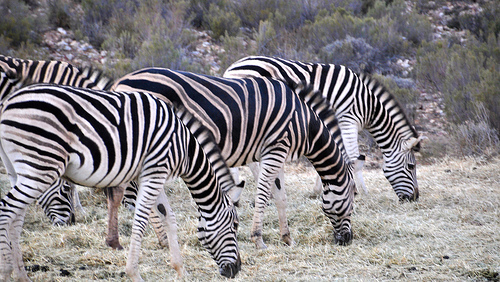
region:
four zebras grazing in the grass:
[1, 20, 441, 277]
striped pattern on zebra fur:
[207, 93, 299, 136]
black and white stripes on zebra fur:
[55, 103, 144, 154]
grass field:
[8, 158, 498, 275]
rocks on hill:
[41, 24, 105, 64]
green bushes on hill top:
[5, 0, 499, 135]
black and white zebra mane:
[280, 73, 365, 180]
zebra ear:
[405, 129, 426, 156]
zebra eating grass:
[2, 77, 249, 280]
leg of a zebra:
[0, 191, 11, 281]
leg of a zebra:
[3, 202, 55, 280]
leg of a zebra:
[92, 185, 139, 267]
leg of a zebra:
[105, 185, 170, 277]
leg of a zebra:
[150, 181, 202, 281]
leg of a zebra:
[263, 176, 308, 250]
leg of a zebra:
[337, 139, 369, 209]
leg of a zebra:
[87, 186, 122, 246]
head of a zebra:
[175, 162, 263, 277]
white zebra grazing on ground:
[0, 84, 240, 275]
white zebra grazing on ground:
[112, 68, 357, 248]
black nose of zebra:
[215, 254, 244, 276]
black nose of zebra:
[332, 227, 352, 248]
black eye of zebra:
[230, 222, 240, 231]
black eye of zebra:
[352, 187, 360, 198]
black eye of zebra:
[404, 159, 414, 169]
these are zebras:
[12, 40, 438, 279]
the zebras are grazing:
[11, 28, 450, 268]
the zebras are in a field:
[7, 30, 481, 280]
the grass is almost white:
[12, 145, 493, 275]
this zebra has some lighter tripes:
[132, 40, 356, 254]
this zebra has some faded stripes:
[108, 60, 363, 265]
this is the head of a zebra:
[189, 182, 259, 280]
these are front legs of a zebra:
[123, 175, 192, 278]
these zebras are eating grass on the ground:
[310, 46, 440, 257]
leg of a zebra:
[0, 192, 28, 277]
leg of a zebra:
[3, 211, 50, 266]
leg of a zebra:
[117, 195, 161, 263]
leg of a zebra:
[102, 193, 153, 235]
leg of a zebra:
[55, 176, 105, 227]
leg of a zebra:
[256, 182, 274, 246]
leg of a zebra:
[265, 182, 297, 242]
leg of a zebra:
[346, 140, 369, 195]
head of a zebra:
[186, 161, 271, 273]